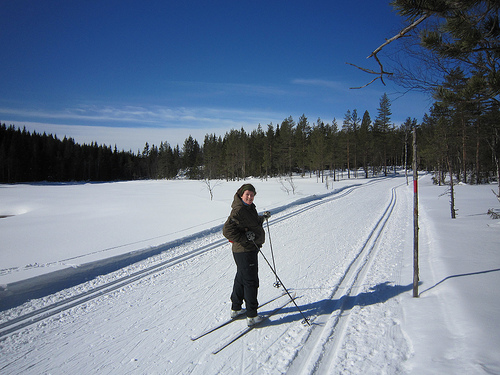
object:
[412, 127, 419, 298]
pole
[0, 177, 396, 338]
tracks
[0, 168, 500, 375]
snow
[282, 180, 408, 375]
tracks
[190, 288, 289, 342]
skis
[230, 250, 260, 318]
pants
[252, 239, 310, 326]
poles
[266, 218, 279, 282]
poles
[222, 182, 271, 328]
skier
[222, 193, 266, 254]
jacket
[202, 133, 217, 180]
trees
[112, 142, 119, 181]
trees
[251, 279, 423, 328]
shadow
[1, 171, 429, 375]
road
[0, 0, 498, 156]
sky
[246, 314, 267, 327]
boots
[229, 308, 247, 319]
boots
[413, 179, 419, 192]
tape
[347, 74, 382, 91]
branch